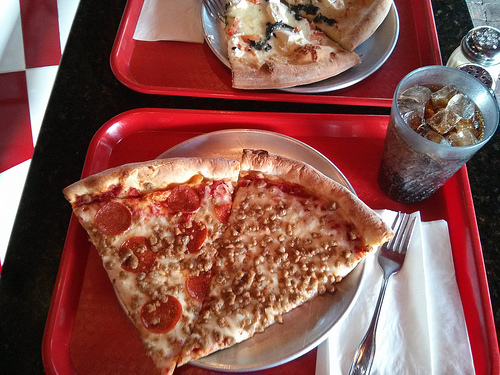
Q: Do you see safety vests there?
A: No, there are no safety vests.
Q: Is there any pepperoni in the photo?
A: Yes, there is pepperoni.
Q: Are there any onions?
A: No, there are no onions.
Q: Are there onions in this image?
A: No, there are no onions.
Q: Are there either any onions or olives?
A: No, there are no onions or olives.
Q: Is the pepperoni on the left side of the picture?
A: Yes, the pepperoni is on the left of the image.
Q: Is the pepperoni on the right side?
A: No, the pepperoni is on the left of the image.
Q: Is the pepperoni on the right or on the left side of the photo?
A: The pepperoni is on the left of the image.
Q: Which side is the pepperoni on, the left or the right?
A: The pepperoni is on the left of the image.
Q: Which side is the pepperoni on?
A: The pepperoni is on the left of the image.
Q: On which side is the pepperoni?
A: The pepperoni is on the left of the image.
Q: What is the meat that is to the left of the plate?
A: The meat is pepperoni.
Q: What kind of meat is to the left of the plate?
A: The meat is pepperoni.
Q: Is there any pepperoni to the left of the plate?
A: Yes, there is pepperoni to the left of the plate.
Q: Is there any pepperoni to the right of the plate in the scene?
A: No, the pepperoni is to the left of the plate.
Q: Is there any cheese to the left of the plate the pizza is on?
A: No, there is pepperoni to the left of the plate.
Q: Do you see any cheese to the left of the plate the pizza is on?
A: No, there is pepperoni to the left of the plate.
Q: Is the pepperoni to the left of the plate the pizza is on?
A: Yes, the pepperoni is to the left of the plate.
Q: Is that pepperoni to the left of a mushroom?
A: No, the pepperoni is to the left of the plate.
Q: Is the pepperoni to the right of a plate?
A: No, the pepperoni is to the left of a plate.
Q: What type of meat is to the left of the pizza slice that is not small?
A: The meat is pepperoni.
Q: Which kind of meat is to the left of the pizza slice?
A: The meat is pepperoni.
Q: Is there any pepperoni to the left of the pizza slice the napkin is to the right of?
A: Yes, there is pepperoni to the left of the pizza slice.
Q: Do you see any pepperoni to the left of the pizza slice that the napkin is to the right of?
A: Yes, there is pepperoni to the left of the pizza slice.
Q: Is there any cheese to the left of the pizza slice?
A: No, there is pepperoni to the left of the pizza slice.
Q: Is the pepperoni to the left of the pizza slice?
A: Yes, the pepperoni is to the left of the pizza slice.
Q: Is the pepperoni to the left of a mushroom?
A: No, the pepperoni is to the left of the pizza slice.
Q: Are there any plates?
A: Yes, there is a plate.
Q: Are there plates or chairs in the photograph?
A: Yes, there is a plate.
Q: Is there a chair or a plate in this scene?
A: Yes, there is a plate.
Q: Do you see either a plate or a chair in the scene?
A: Yes, there is a plate.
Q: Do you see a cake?
A: No, there are no cakes.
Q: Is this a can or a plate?
A: This is a plate.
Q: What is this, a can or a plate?
A: This is a plate.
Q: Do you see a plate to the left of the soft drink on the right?
A: Yes, there is a plate to the left of the soft drink.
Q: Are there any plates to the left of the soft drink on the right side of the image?
A: Yes, there is a plate to the left of the soft drink.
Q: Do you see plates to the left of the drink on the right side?
A: Yes, there is a plate to the left of the soft drink.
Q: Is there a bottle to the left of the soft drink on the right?
A: No, there is a plate to the left of the soft drink.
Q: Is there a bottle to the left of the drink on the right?
A: No, there is a plate to the left of the soft drink.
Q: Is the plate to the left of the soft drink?
A: Yes, the plate is to the left of the soft drink.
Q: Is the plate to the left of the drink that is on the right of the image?
A: Yes, the plate is to the left of the soft drink.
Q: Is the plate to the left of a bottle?
A: No, the plate is to the left of the soft drink.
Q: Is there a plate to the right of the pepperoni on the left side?
A: Yes, there is a plate to the right of the pepperoni.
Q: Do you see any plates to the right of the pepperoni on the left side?
A: Yes, there is a plate to the right of the pepperoni.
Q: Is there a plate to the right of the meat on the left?
A: Yes, there is a plate to the right of the pepperoni.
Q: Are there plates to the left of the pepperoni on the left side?
A: No, the plate is to the right of the pepperoni.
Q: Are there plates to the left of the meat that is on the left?
A: No, the plate is to the right of the pepperoni.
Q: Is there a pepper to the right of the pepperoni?
A: No, there is a plate to the right of the pepperoni.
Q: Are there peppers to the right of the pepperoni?
A: No, there is a plate to the right of the pepperoni.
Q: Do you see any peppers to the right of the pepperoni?
A: No, there is a plate to the right of the pepperoni.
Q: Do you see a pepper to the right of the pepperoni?
A: No, there is a plate to the right of the pepperoni.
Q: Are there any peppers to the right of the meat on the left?
A: No, there is a plate to the right of the pepperoni.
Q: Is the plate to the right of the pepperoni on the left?
A: Yes, the plate is to the right of the pepperoni.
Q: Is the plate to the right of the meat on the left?
A: Yes, the plate is to the right of the pepperoni.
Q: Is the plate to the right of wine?
A: No, the plate is to the right of the pepperoni.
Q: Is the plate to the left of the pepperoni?
A: No, the plate is to the right of the pepperoni.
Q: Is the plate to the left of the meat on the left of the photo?
A: No, the plate is to the right of the pepperoni.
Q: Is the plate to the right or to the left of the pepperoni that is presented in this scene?
A: The plate is to the right of the pepperoni.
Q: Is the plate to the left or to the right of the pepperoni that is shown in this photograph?
A: The plate is to the right of the pepperoni.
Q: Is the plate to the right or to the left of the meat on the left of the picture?
A: The plate is to the right of the pepperoni.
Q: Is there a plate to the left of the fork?
A: Yes, there is a plate to the left of the fork.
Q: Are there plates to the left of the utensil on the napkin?
A: Yes, there is a plate to the left of the fork.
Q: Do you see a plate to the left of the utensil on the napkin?
A: Yes, there is a plate to the left of the fork.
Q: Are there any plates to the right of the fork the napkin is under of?
A: No, the plate is to the left of the fork.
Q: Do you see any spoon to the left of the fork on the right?
A: No, there is a plate to the left of the fork.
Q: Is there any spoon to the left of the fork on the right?
A: No, there is a plate to the left of the fork.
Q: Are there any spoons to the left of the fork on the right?
A: No, there is a plate to the left of the fork.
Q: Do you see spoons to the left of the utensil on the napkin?
A: No, there is a plate to the left of the fork.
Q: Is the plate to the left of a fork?
A: Yes, the plate is to the left of a fork.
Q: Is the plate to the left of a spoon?
A: No, the plate is to the left of a fork.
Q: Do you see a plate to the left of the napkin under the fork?
A: Yes, there is a plate to the left of the napkin.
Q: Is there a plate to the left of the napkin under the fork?
A: Yes, there is a plate to the left of the napkin.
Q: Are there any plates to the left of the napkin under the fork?
A: Yes, there is a plate to the left of the napkin.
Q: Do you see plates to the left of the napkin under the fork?
A: Yes, there is a plate to the left of the napkin.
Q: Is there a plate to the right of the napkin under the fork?
A: No, the plate is to the left of the napkin.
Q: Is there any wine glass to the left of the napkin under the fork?
A: No, there is a plate to the left of the napkin.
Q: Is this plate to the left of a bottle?
A: No, the plate is to the left of the napkin.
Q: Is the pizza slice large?
A: Yes, the pizza slice is large.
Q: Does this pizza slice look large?
A: Yes, the pizza slice is large.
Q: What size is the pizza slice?
A: The pizza slice is large.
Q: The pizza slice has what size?
A: The pizza slice is large.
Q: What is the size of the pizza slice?
A: The pizza slice is large.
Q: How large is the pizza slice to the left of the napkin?
A: The pizza slice is large.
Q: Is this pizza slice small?
A: No, the pizza slice is large.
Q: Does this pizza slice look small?
A: No, the pizza slice is large.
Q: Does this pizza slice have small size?
A: No, the pizza slice is large.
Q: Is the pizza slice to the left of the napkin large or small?
A: The pizza slice is large.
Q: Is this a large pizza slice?
A: Yes, this is a large pizza slice.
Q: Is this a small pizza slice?
A: No, this is a large pizza slice.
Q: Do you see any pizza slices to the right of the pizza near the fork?
A: Yes, there is a pizza slice to the right of the pizza.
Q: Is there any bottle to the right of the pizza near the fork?
A: No, there is a pizza slice to the right of the pizza.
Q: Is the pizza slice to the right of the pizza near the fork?
A: Yes, the pizza slice is to the right of the pizza.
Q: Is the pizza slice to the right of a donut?
A: No, the pizza slice is to the right of the pizza.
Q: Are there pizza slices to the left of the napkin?
A: Yes, there is a pizza slice to the left of the napkin.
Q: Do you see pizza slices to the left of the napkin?
A: Yes, there is a pizza slice to the left of the napkin.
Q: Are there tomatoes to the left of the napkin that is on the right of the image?
A: No, there is a pizza slice to the left of the napkin.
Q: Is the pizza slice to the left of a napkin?
A: Yes, the pizza slice is to the left of a napkin.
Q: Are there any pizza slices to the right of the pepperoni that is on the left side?
A: Yes, there is a pizza slice to the right of the pepperoni.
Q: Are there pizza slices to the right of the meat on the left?
A: Yes, there is a pizza slice to the right of the pepperoni.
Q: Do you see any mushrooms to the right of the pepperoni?
A: No, there is a pizza slice to the right of the pepperoni.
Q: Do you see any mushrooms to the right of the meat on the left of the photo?
A: No, there is a pizza slice to the right of the pepperoni.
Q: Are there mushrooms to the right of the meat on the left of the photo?
A: No, there is a pizza slice to the right of the pepperoni.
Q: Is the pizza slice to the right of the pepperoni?
A: Yes, the pizza slice is to the right of the pepperoni.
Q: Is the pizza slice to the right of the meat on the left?
A: Yes, the pizza slice is to the right of the pepperoni.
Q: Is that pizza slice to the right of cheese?
A: No, the pizza slice is to the right of the pepperoni.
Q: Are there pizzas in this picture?
A: Yes, there is a pizza.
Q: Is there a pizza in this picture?
A: Yes, there is a pizza.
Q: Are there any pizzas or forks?
A: Yes, there is a pizza.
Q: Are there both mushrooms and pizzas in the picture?
A: No, there is a pizza but no mushrooms.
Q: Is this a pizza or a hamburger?
A: This is a pizza.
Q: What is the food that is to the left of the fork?
A: The food is a pizza.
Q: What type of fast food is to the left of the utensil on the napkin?
A: The food is a pizza.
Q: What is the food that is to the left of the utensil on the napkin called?
A: The food is a pizza.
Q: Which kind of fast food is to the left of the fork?
A: The food is a pizza.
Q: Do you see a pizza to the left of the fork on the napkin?
A: Yes, there is a pizza to the left of the fork.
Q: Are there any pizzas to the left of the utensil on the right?
A: Yes, there is a pizza to the left of the fork.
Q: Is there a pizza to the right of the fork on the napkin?
A: No, the pizza is to the left of the fork.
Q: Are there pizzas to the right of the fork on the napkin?
A: No, the pizza is to the left of the fork.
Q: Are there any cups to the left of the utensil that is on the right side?
A: No, there is a pizza to the left of the fork.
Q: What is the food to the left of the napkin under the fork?
A: The food is a pizza.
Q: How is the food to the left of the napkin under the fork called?
A: The food is a pizza.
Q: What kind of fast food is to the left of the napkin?
A: The food is a pizza.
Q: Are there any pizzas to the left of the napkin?
A: Yes, there is a pizza to the left of the napkin.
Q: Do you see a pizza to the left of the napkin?
A: Yes, there is a pizza to the left of the napkin.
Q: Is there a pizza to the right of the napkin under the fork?
A: No, the pizza is to the left of the napkin.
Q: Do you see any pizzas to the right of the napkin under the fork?
A: No, the pizza is to the left of the napkin.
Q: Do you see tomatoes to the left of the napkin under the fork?
A: No, there is a pizza to the left of the napkin.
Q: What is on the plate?
A: The pizza is on the plate.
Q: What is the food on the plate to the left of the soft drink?
A: The food is a pizza.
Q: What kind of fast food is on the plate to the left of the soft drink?
A: The food is a pizza.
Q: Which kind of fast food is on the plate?
A: The food is a pizza.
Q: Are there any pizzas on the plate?
A: Yes, there is a pizza on the plate.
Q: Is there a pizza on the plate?
A: Yes, there is a pizza on the plate.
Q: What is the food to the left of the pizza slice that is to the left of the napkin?
A: The food is a pizza.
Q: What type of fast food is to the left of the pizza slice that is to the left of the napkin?
A: The food is a pizza.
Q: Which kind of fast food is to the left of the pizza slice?
A: The food is a pizza.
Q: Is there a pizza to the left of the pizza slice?
A: Yes, there is a pizza to the left of the pizza slice.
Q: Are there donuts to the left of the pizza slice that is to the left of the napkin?
A: No, there is a pizza to the left of the pizza slice.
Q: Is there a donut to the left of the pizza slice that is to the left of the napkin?
A: No, there is a pizza to the left of the pizza slice.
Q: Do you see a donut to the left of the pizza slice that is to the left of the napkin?
A: No, there is a pizza to the left of the pizza slice.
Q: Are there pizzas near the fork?
A: Yes, there is a pizza near the fork.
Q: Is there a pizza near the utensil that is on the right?
A: Yes, there is a pizza near the fork.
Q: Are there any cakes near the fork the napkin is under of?
A: No, there is a pizza near the fork.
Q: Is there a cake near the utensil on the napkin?
A: No, there is a pizza near the fork.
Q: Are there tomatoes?
A: No, there are no tomatoes.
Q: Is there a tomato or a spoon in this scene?
A: No, there are no tomatoes or spoons.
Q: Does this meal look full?
A: Yes, the meal is full.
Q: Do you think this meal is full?
A: Yes, the meal is full.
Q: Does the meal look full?
A: Yes, the meal is full.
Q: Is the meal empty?
A: No, the meal is full.